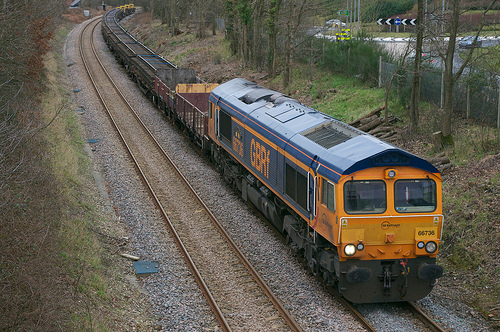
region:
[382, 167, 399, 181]
a head light of a train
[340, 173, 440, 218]
The front windows of a train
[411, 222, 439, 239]
Numbers painted on the front of a train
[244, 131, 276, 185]
GBRf written on the side of a train engine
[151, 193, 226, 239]
Metal train rails on wood and gravel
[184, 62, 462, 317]
A train travelling down the tracks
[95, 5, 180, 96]
Many train cars being pulled by an engine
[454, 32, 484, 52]
A car on a road near train tracks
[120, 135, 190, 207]
An empty train track.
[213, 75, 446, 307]
The orange train engine.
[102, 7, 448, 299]
A train.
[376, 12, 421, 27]
A road directional sign.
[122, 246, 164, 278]
Trash on the side.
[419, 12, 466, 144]
A tree on the side of the tracks.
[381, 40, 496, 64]
A street behind the trees.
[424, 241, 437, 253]
A blown light bulb.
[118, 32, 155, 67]
Coal transporters.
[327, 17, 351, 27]
A car in a driveway.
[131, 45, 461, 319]
yellow and blue train on train tracks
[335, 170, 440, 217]
two windows on front of train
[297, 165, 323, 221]
two metal rails on side of train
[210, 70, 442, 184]
blue triangular roof on top of train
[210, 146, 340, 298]
black wheels on bottom of train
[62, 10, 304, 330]
brown metal train tracks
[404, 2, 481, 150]
brown tree trunks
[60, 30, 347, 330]
grey gravel surrounding train tracks on ground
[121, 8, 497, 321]
grass covered hill on side of train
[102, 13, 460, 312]
Train on railway tracks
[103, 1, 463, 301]
A cargo train on railway tracks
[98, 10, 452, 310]
Orange and blue train on railway tracks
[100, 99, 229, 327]
Railway tracks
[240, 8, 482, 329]
Trees next to railway tracks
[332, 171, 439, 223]
Train windshield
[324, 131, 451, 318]
Blue, orange and black train car face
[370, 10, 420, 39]
Road arrow signs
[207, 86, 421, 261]
a long train on the tracks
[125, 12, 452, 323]
a train on train tracks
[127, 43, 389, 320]
tracks with a train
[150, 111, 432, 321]
tracks with a long train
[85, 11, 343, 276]
train tracks with long train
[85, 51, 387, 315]
train moving on the tracks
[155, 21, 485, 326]
train moving on the train tracks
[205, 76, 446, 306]
train is blue and yellow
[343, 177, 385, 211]
window on front of train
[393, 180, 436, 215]
window on front of train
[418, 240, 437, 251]
headlight on front of train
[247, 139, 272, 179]
logo on side of train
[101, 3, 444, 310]
train moves along tracks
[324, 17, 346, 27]
car behind train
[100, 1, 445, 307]
train in front of car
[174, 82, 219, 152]
cart pulled by train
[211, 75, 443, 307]
the train is orange in color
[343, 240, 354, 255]
the headlight is turned on